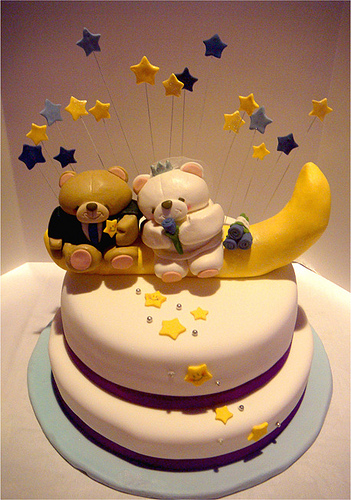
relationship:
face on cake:
[183, 363, 213, 387] [26, 151, 349, 478]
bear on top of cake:
[42, 166, 140, 273] [16, 27, 334, 497]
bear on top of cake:
[131, 156, 231, 282] [16, 27, 334, 497]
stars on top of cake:
[16, 26, 331, 170] [26, 164, 332, 498]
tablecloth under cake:
[3, 259, 348, 498] [26, 164, 332, 498]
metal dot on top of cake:
[137, 288, 142, 294] [26, 164, 332, 498]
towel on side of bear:
[223, 217, 247, 241] [42, 166, 140, 273]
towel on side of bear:
[235, 233, 255, 250] [131, 156, 231, 282]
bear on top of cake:
[131, 156, 231, 282] [46, 264, 315, 472]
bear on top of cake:
[42, 166, 140, 273] [46, 264, 315, 472]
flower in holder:
[161, 216, 183, 254] [158, 225, 186, 254]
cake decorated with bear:
[39, 215, 326, 472] [131, 156, 231, 282]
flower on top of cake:
[221, 214, 254, 251] [16, 27, 334, 497]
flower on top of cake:
[221, 173, 324, 251] [16, 27, 334, 497]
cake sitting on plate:
[43, 163, 333, 475] [26, 331, 344, 491]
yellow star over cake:
[64, 94, 88, 118] [0, 214, 349, 497]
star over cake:
[301, 92, 334, 125] [39, 215, 326, 472]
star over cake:
[220, 111, 244, 136] [16, 27, 334, 497]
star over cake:
[122, 54, 162, 86] [31, 173, 330, 469]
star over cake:
[254, 143, 273, 162] [45, 211, 313, 463]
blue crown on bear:
[150, 159, 172, 178] [131, 156, 231, 282]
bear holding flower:
[135, 156, 231, 283] [157, 212, 188, 257]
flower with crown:
[157, 212, 188, 257] [145, 156, 173, 178]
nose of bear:
[80, 207, 104, 221] [46, 167, 152, 287]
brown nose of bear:
[160, 195, 173, 212] [131, 156, 231, 282]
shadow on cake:
[71, 278, 231, 300] [39, 215, 326, 472]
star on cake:
[131, 282, 269, 447] [17, 196, 333, 498]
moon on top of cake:
[43, 163, 332, 280] [26, 151, 349, 478]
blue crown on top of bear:
[150, 159, 172, 178] [131, 156, 231, 282]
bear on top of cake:
[131, 156, 231, 282] [43, 163, 333, 475]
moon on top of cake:
[43, 163, 332, 280] [43, 163, 333, 475]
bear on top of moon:
[131, 156, 231, 282] [43, 163, 332, 280]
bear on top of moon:
[42, 166, 140, 273] [43, 163, 332, 280]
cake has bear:
[43, 163, 333, 475] [131, 156, 231, 282]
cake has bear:
[43, 163, 333, 475] [42, 166, 140, 273]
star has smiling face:
[192, 25, 226, 67] [189, 369, 204, 381]